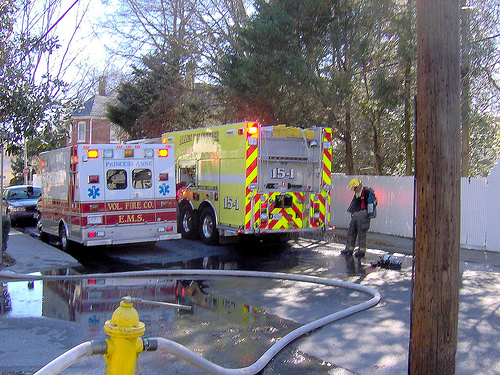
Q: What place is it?
A: It is a road.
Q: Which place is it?
A: It is a road.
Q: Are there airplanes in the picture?
A: No, there are no airplanes.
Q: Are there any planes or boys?
A: No, there are no planes or boys.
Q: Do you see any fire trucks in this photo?
A: Yes, there is a fire truck.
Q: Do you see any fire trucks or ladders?
A: Yes, there is a fire truck.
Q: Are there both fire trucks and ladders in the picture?
A: No, there is a fire truck but no ladders.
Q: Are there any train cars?
A: No, there are no train cars.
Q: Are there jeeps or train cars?
A: No, there are no train cars or jeeps.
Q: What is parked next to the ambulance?
A: The fire truck is parked next to the ambulance.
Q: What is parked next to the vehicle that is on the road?
A: The fire truck is parked next to the ambulance.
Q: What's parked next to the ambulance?
A: The fire truck is parked next to the ambulance.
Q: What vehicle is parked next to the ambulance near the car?
A: The vehicle is a fire truck.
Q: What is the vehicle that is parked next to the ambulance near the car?
A: The vehicle is a fire truck.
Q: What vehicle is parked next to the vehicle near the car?
A: The vehicle is a fire truck.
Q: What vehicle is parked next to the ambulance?
A: The vehicle is a fire truck.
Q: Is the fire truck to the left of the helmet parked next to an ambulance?
A: Yes, the fire truck is parked next to an ambulance.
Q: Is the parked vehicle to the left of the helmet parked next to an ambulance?
A: Yes, the fire truck is parked next to an ambulance.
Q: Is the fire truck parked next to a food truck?
A: No, the fire truck is parked next to an ambulance.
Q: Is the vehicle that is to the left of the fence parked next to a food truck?
A: No, the fire truck is parked next to an ambulance.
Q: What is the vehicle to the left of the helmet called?
A: The vehicle is a fire truck.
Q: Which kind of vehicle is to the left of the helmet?
A: The vehicle is a fire truck.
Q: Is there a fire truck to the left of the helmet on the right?
A: Yes, there is a fire truck to the left of the helmet.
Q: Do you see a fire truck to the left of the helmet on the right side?
A: Yes, there is a fire truck to the left of the helmet.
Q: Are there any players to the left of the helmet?
A: No, there is a fire truck to the left of the helmet.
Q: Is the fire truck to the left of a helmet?
A: Yes, the fire truck is to the left of a helmet.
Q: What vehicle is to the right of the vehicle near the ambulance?
A: The vehicle is a fire truck.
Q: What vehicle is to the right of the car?
A: The vehicle is a fire truck.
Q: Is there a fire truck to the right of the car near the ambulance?
A: Yes, there is a fire truck to the right of the car.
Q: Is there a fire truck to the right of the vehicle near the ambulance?
A: Yes, there is a fire truck to the right of the car.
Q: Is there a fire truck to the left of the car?
A: No, the fire truck is to the right of the car.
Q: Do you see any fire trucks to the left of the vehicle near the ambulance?
A: No, the fire truck is to the right of the car.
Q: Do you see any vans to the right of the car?
A: No, there is a fire truck to the right of the car.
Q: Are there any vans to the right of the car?
A: No, there is a fire truck to the right of the car.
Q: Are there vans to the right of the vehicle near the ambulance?
A: No, there is a fire truck to the right of the car.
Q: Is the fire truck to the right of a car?
A: Yes, the fire truck is to the right of a car.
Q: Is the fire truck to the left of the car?
A: No, the fire truck is to the right of the car.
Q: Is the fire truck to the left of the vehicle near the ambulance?
A: No, the fire truck is to the right of the car.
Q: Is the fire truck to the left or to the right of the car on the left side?
A: The fire truck is to the right of the car.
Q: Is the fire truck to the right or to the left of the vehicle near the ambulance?
A: The fire truck is to the right of the car.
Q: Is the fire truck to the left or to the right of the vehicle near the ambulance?
A: The fire truck is to the right of the car.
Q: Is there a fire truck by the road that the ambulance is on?
A: Yes, there is a fire truck by the road.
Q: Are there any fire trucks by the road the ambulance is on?
A: Yes, there is a fire truck by the road.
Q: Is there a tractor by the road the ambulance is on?
A: No, there is a fire truck by the road.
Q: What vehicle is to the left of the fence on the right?
A: The vehicle is a fire truck.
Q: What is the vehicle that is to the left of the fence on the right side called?
A: The vehicle is a fire truck.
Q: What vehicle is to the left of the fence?
A: The vehicle is a fire truck.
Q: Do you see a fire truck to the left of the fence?
A: Yes, there is a fire truck to the left of the fence.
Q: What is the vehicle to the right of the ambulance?
A: The vehicle is a fire truck.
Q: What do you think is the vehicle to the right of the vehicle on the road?
A: The vehicle is a fire truck.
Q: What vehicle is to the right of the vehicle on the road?
A: The vehicle is a fire truck.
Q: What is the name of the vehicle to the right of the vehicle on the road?
A: The vehicle is a fire truck.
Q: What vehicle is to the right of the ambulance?
A: The vehicle is a fire truck.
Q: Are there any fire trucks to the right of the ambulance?
A: Yes, there is a fire truck to the right of the ambulance.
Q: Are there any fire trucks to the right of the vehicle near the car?
A: Yes, there is a fire truck to the right of the ambulance.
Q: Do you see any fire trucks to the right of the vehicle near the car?
A: Yes, there is a fire truck to the right of the ambulance.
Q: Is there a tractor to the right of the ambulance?
A: No, there is a fire truck to the right of the ambulance.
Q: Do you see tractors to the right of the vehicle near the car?
A: No, there is a fire truck to the right of the ambulance.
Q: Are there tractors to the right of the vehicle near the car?
A: No, there is a fire truck to the right of the ambulance.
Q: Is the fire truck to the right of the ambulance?
A: Yes, the fire truck is to the right of the ambulance.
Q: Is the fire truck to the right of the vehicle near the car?
A: Yes, the fire truck is to the right of the ambulance.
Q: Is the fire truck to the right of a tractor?
A: No, the fire truck is to the right of the ambulance.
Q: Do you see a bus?
A: No, there are no buses.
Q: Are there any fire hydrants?
A: Yes, there is a fire hydrant.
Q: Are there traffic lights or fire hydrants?
A: Yes, there is a fire hydrant.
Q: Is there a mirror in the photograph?
A: No, there are no mirrors.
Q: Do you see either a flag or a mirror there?
A: No, there are no mirrors or flags.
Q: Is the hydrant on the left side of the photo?
A: Yes, the hydrant is on the left of the image.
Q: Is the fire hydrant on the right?
A: No, the fire hydrant is on the left of the image.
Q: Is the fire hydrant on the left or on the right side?
A: The fire hydrant is on the left of the image.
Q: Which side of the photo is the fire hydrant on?
A: The fire hydrant is on the left of the image.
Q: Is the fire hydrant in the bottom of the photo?
A: Yes, the fire hydrant is in the bottom of the image.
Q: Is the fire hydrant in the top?
A: No, the fire hydrant is in the bottom of the image.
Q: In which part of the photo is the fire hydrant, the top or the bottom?
A: The fire hydrant is in the bottom of the image.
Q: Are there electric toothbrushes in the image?
A: No, there are no electric toothbrushes.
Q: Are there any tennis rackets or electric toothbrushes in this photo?
A: No, there are no electric toothbrushes or tennis rackets.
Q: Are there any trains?
A: No, there are no trains.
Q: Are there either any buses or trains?
A: No, there are no trains or buses.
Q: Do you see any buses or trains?
A: No, there are no trains or buses.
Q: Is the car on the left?
A: Yes, the car is on the left of the image.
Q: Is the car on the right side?
A: No, the car is on the left of the image.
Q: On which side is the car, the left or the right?
A: The car is on the left of the image.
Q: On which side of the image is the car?
A: The car is on the left of the image.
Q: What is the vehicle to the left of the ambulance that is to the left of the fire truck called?
A: The vehicle is a car.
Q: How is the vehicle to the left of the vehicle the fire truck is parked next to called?
A: The vehicle is a car.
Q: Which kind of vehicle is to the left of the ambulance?
A: The vehicle is a car.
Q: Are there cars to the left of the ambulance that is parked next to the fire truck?
A: Yes, there is a car to the left of the ambulance.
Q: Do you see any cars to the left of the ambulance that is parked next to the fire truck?
A: Yes, there is a car to the left of the ambulance.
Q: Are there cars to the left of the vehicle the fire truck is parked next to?
A: Yes, there is a car to the left of the ambulance.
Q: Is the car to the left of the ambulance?
A: Yes, the car is to the left of the ambulance.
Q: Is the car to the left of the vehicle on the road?
A: Yes, the car is to the left of the ambulance.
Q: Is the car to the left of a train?
A: No, the car is to the left of the ambulance.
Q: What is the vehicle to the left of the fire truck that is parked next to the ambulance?
A: The vehicle is a car.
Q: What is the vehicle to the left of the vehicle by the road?
A: The vehicle is a car.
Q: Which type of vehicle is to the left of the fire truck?
A: The vehicle is a car.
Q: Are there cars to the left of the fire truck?
A: Yes, there is a car to the left of the fire truck.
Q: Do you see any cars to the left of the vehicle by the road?
A: Yes, there is a car to the left of the fire truck.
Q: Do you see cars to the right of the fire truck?
A: No, the car is to the left of the fire truck.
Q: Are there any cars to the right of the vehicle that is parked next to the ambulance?
A: No, the car is to the left of the fire truck.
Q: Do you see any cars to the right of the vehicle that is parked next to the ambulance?
A: No, the car is to the left of the fire truck.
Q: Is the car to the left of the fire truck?
A: Yes, the car is to the left of the fire truck.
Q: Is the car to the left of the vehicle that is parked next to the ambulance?
A: Yes, the car is to the left of the fire truck.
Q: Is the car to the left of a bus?
A: No, the car is to the left of the fire truck.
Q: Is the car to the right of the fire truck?
A: No, the car is to the left of the fire truck.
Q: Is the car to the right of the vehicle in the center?
A: No, the car is to the left of the fire truck.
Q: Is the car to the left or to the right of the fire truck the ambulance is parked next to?
A: The car is to the left of the fire truck.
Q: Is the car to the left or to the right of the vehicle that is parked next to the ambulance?
A: The car is to the left of the fire truck.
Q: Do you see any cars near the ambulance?
A: Yes, there is a car near the ambulance.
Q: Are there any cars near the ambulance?
A: Yes, there is a car near the ambulance.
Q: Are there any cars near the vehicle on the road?
A: Yes, there is a car near the ambulance.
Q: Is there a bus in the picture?
A: No, there are no buses.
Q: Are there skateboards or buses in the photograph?
A: No, there are no buses or skateboards.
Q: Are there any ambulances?
A: Yes, there is an ambulance.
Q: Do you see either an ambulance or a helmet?
A: Yes, there is an ambulance.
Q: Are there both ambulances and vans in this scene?
A: No, there is an ambulance but no vans.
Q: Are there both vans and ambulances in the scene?
A: No, there is an ambulance but no vans.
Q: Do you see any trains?
A: No, there are no trains.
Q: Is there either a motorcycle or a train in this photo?
A: No, there are no trains or motorcycles.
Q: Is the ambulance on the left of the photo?
A: Yes, the ambulance is on the left of the image.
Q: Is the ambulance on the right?
A: No, the ambulance is on the left of the image.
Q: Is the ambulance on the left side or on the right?
A: The ambulance is on the left of the image.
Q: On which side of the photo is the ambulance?
A: The ambulance is on the left of the image.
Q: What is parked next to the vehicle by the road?
A: The ambulance is parked next to the fire truck.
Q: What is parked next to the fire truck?
A: The ambulance is parked next to the fire truck.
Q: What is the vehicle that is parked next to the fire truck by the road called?
A: The vehicle is an ambulance.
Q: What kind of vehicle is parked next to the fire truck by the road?
A: The vehicle is an ambulance.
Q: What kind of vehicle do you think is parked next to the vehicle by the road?
A: The vehicle is an ambulance.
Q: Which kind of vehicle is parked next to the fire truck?
A: The vehicle is an ambulance.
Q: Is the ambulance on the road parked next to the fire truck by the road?
A: Yes, the ambulance is parked next to the fire truck.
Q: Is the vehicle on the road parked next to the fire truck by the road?
A: Yes, the ambulance is parked next to the fire truck.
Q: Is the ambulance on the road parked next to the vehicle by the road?
A: Yes, the ambulance is parked next to the fire truck.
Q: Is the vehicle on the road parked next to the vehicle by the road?
A: Yes, the ambulance is parked next to the fire truck.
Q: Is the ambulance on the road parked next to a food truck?
A: No, the ambulance is parked next to the fire truck.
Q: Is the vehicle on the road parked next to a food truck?
A: No, the ambulance is parked next to the fire truck.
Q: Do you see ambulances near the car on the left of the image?
A: Yes, there is an ambulance near the car.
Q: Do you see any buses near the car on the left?
A: No, there is an ambulance near the car.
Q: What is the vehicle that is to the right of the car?
A: The vehicle is an ambulance.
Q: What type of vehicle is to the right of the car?
A: The vehicle is an ambulance.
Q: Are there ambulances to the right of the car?
A: Yes, there is an ambulance to the right of the car.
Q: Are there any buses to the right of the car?
A: No, there is an ambulance to the right of the car.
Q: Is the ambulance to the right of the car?
A: Yes, the ambulance is to the right of the car.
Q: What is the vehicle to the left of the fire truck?
A: The vehicle is an ambulance.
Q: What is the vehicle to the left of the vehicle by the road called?
A: The vehicle is an ambulance.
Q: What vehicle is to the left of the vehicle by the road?
A: The vehicle is an ambulance.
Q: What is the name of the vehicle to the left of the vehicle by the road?
A: The vehicle is an ambulance.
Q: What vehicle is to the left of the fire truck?
A: The vehicle is an ambulance.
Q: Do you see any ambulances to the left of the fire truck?
A: Yes, there is an ambulance to the left of the fire truck.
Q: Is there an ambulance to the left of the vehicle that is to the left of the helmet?
A: Yes, there is an ambulance to the left of the fire truck.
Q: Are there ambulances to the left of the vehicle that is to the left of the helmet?
A: Yes, there is an ambulance to the left of the fire truck.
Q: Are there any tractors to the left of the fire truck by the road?
A: No, there is an ambulance to the left of the fire truck.